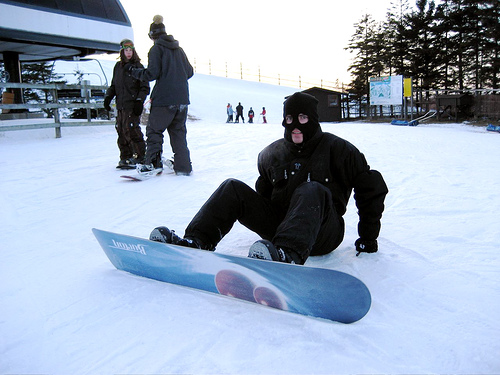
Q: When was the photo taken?
A: Afternoon.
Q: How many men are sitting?
A: One.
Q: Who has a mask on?
A: The man.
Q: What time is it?
A: Afternoon.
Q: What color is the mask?
A: Black.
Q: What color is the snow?
A: White.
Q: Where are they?
A: On a ski slope.